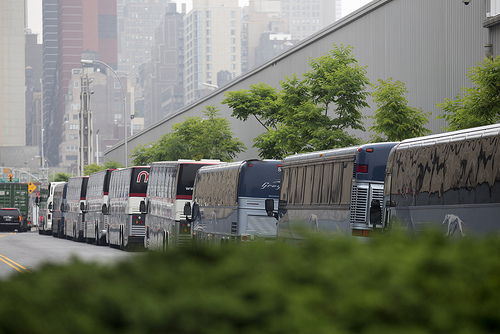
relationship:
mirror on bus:
[265, 199, 275, 211] [254, 130, 411, 254]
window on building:
[202, 13, 209, 18] [178, 3, 240, 105]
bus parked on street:
[35, 123, 500, 253] [0, 233, 147, 278]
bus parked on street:
[185, 160, 254, 215] [0, 233, 147, 278]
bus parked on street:
[65, 171, 97, 213] [0, 233, 147, 278]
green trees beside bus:
[229, 45, 424, 142] [271, 139, 399, 234]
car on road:
[0, 208, 23, 232] [0, 230, 144, 277]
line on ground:
[66, 198, 156, 277] [33, 157, 420, 326]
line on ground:
[1, 242, 39, 277] [1, 230, 159, 282]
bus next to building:
[380, 117, 497, 237] [92, 4, 499, 169]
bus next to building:
[35, 123, 500, 253] [92, 4, 499, 169]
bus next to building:
[136, 150, 226, 252] [92, 4, 499, 169]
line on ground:
[0, 232, 34, 276] [1, 225, 498, 331]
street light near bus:
[90, 122, 107, 167] [101, 165, 145, 250]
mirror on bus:
[265, 201, 275, 211] [267, 135, 390, 235]